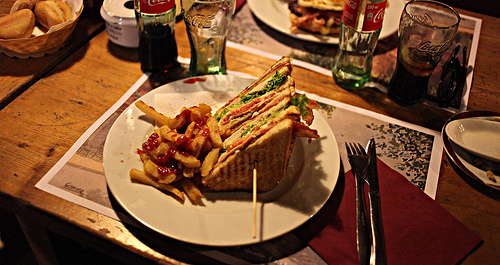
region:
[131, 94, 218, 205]
fries covered in ketchup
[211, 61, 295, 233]
a grilled sandwich on a stick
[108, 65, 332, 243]
a delicious plate of food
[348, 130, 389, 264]
a fork and knife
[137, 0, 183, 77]
a half empty bottle of coke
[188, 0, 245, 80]
an empty glass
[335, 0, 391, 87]
an empty bottle of coke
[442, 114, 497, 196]
an empty plate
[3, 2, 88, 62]
a bowl of bread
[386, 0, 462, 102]
a half empty glass of coke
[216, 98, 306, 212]
sandwich with toothpick in it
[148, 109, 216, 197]
french fries with ketchup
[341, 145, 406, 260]
utensils on maroon napkin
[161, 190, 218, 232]
dinner plate is white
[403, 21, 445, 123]
glass with coca cola emblem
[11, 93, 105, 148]
table is brown and scarred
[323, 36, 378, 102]
coke bottle is empty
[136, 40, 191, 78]
coke bottle half full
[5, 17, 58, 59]
basket with dinner rolls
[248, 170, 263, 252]
stick in club sandwich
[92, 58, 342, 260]
sandwich and fries on plate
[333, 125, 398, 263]
utensils on a table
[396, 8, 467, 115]
glass of soda on table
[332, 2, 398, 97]
bottle of coke on table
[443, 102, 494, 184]
plate on the table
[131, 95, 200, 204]
fries on a plate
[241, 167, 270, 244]
toothpick in a sandwich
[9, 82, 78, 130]
wooden table where food is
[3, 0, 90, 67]
bread rolls in a basket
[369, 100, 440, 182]
placemat on a table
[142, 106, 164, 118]
FRIES ON THE PLANT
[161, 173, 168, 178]
KETCHUP ON THE FRIES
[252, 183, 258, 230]
STICK IN THE SANDWICH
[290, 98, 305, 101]
HEALTHY GREEN LEAF LETTUCE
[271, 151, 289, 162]
WHITE TOASTED BREAD ON THE PLATE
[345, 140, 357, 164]
FORK IS ON THE TABLE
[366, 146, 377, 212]
BUTTER KNIFE ON THE NAPKIN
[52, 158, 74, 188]
MAT IS ON THE TABLE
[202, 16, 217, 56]
GLASS ON THE TABLE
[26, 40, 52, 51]
BASKET IS SETTING ON THE TABLE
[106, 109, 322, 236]
white plate on table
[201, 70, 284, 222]
large sandwich on plate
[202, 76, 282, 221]
sandwich is diagonally sliced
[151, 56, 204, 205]
french fries on plate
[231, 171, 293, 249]
wood skewer in sandwich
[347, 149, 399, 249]
knife and fork on napkin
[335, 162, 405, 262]
red napkin on paper placemat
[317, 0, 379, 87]
glass bottle of soda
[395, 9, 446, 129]
clear glass cup next to soda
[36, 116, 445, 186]
paper mat on table